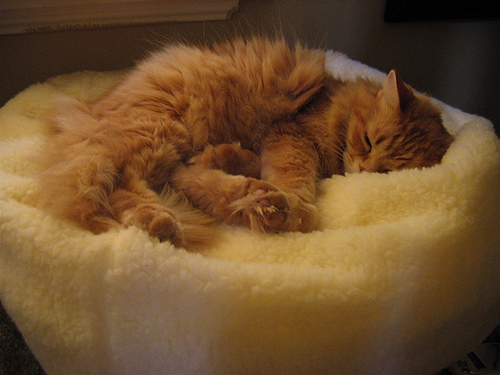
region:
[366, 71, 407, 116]
Cat has tan ear.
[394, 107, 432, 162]
Cat has stripes on head.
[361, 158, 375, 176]
Cat has tan nose.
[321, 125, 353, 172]
Cat has white whiskers.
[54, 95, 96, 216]
Cat has tan tail.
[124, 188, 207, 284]
Cat has tan paw.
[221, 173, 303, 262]
Cat has tan paw.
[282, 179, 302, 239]
Cat has tan paw.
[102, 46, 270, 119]
Cat has tan side.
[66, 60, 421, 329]
Cat is laying on white bed.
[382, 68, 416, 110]
ear of a cat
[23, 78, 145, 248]
tail of a cat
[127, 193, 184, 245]
paw of a cat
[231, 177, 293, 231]
paw of a cat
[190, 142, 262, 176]
paw of a cat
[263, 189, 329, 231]
paw of a cat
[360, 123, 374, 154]
eye of a cat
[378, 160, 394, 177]
eye of a cat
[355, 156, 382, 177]
nose of a cat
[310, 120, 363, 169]
whiskers of a cat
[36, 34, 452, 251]
a cat sleeping on a soft bed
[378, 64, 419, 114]
the ear of a cat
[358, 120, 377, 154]
the eye of a cat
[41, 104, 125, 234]
the tail of a cat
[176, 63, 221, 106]
the fur of a cat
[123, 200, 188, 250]
the paw of a cat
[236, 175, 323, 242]
the paws of a cat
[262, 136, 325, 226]
the leg of a cat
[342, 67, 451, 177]
the head of a cat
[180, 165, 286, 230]
the leg of a cat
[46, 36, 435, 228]
the cat is sleeping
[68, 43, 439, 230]
the cat is cute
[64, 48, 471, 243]
the cat is peaceful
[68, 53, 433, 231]
the cat is orange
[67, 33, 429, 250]
the cat is fluffy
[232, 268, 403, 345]
the bed is white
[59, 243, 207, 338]
the bed is soft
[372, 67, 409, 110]
the ear is pointy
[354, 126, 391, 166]
the eyes are closed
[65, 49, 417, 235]
the cat is soft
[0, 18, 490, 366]
Orange cat sleeping on cat bed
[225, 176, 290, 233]
Rear paw of orange cat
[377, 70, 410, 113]
An orange cat's right ear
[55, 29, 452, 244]
A fluffy, white and orange cat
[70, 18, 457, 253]
A cat sleeping peacefully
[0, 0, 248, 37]
A piece opf window trip with paint on it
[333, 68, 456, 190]
Face of a sleeping cat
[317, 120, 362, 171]
Whiskers of a sleeping cat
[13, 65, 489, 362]
A soft and fluffy cat bed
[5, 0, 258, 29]
A piece of white trim with brown wall paint on the bottom